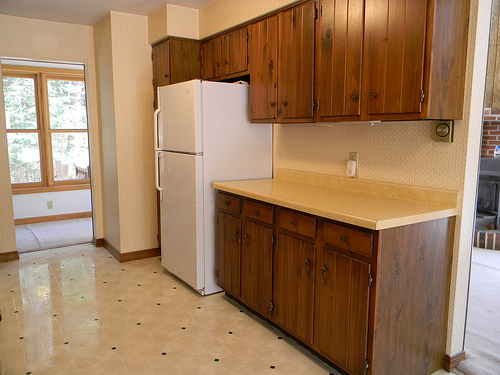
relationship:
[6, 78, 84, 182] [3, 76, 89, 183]
tree outside of window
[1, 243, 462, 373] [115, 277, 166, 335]
floor has pattern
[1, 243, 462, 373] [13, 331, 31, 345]
floor has part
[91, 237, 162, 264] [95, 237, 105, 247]
trimming has part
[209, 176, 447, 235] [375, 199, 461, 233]
surface has edge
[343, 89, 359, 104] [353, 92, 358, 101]
handle has part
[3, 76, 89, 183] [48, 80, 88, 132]
window has part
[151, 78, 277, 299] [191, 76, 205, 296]
refrigerator has edge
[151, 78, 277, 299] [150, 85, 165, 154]
refrigerator has part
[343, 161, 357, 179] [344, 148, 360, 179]
air freshener plugged into outlet